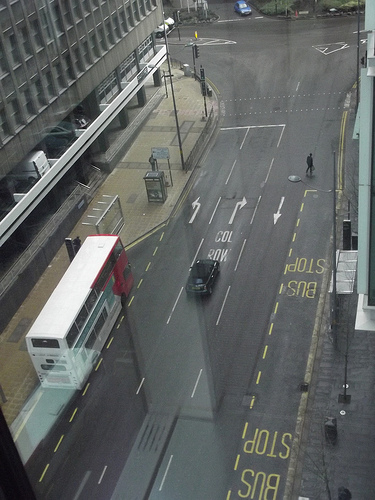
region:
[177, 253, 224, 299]
A car driving down the street.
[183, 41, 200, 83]
A stoplight at the corner of an intersection.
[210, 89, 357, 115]
A crosswalk on a city street.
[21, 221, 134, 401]
A bus parked at a bus stop.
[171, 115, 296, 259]
White lines painted on a road.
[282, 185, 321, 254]
Yellow lines painted on a street.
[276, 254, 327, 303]
The words BUS STOP painted on a road.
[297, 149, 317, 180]
Man walking across a street.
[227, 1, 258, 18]
Blue car driving down the road.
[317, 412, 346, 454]
A garbage can on the sidewalk.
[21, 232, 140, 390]
Double decker bus on side of road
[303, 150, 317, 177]
Pedestrian crossing the steet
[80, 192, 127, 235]
Metal and glass bus stop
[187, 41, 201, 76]
Traffic signal post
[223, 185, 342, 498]
Bus stop traffic lane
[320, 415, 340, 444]
Metal trash can on sidewalk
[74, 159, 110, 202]
Stairway entrance into building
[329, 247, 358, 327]
Bus stop waiting area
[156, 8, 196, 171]
Metal street light pole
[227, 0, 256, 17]
Car waiting at intersection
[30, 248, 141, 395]
the bus is parked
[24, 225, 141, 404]
the bus is double decker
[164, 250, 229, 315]
the car is black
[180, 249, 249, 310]
the car is on road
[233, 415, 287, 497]
the words are golden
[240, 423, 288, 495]
the words on the road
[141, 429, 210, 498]
the lines are white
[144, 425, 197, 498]
the lines on the road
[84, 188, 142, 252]
bus stop on sidewalk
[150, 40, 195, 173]
light post on sidewalk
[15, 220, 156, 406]
This is a bus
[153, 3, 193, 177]
This is a post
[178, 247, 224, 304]
This is a car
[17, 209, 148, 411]
This is a double Decker bus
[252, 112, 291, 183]
White markings on the road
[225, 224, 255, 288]
White markings on the road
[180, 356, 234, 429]
White markings on the road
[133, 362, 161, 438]
White markings on the road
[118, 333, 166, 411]
White markings on the road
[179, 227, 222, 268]
White markings on the road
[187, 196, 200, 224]
the white arrow on the road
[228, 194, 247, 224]
the white arrow on the road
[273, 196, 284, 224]
the white arrow on the road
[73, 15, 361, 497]
the white lines on the road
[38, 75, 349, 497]
the yellow lines on the road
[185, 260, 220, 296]
the car on the road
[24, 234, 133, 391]
the large bus on the road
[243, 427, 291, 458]
the word STOP on the road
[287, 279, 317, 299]
the word BUS on the road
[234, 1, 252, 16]
the blue car on the road